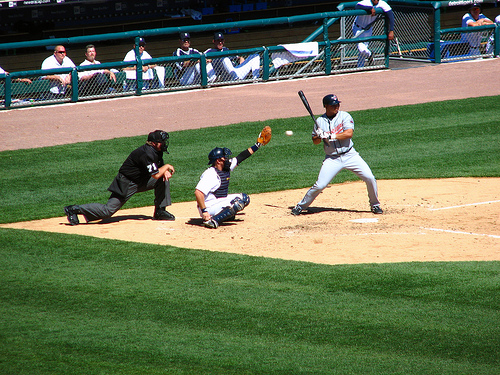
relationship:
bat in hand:
[298, 90, 331, 147] [314, 128, 324, 148]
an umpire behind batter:
[63, 129, 176, 225] [294, 79, 384, 221]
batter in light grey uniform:
[294, 79, 384, 221] [290, 111, 387, 230]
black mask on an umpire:
[135, 120, 184, 161] [63, 129, 176, 225]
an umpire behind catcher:
[45, 110, 197, 243] [178, 118, 278, 229]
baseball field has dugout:
[8, 26, 498, 373] [4, 3, 498, 108]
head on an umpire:
[142, 123, 180, 152] [63, 129, 176, 225]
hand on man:
[250, 120, 271, 155] [202, 111, 270, 245]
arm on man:
[193, 159, 217, 229] [186, 125, 275, 226]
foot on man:
[283, 199, 313, 220] [297, 84, 379, 214]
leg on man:
[289, 150, 348, 222] [289, 76, 390, 218]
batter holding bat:
[291, 93, 384, 215] [291, 80, 326, 134]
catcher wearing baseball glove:
[194, 125, 272, 228] [316, 127, 338, 145]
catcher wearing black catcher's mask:
[194, 125, 272, 228] [222, 160, 232, 172]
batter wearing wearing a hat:
[291, 93, 384, 215] [320, 90, 347, 120]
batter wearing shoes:
[291, 93, 384, 215] [283, 197, 395, 213]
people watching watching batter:
[31, 20, 280, 109] [291, 93, 384, 215]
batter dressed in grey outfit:
[291, 93, 384, 215] [286, 83, 420, 243]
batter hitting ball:
[291, 93, 384, 215] [282, 125, 293, 139]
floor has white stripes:
[5, 82, 497, 370] [281, 79, 396, 230]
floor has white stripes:
[5, 82, 497, 370] [358, 190, 497, 269]